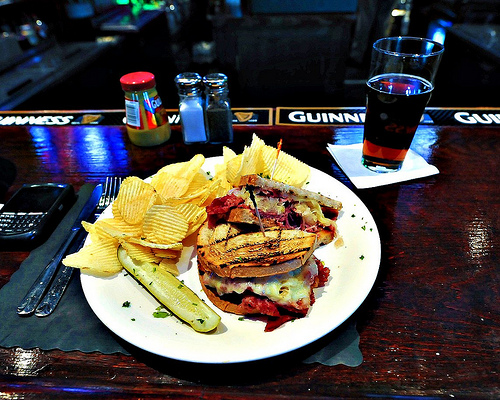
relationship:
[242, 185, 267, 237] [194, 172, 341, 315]
toothpick in sandwich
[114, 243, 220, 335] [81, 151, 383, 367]
pickle on plate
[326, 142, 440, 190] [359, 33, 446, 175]
napkin under drink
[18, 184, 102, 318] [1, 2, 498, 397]
knife on table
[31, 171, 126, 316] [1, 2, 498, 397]
fork on table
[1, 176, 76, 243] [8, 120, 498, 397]
cell phone on top of bar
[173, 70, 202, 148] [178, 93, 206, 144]
shaker of salt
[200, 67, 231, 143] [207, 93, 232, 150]
shaker of pepper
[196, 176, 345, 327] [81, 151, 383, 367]
sandwich on a plate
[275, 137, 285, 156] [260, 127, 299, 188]
top of toothpick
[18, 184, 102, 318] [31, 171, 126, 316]
knife beside fork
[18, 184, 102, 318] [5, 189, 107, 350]
knife on place mat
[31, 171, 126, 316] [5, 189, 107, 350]
fork on place mat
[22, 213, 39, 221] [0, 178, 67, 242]
buttons on cell phone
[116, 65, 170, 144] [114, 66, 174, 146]
condiment in jar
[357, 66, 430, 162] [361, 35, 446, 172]
liquid in glass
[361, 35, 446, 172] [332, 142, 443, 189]
glass on a napkin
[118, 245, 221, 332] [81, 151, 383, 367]
food on a plate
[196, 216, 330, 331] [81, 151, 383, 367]
food on a plate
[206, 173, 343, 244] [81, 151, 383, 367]
food on a plate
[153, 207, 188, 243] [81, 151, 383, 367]
food on a plate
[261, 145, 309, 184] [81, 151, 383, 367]
food on a plate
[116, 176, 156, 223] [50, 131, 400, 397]
chip on a plate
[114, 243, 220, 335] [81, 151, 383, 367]
pickle on a plate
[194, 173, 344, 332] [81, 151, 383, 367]
sandwich on plate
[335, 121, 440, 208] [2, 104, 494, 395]
napkin on table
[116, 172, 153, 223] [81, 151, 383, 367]
chip on plate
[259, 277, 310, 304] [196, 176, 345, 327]
cheese on sandwich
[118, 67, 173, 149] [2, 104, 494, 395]
mustard on table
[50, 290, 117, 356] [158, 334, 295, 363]
place mat under plate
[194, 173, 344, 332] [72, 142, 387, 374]
sandwich on plate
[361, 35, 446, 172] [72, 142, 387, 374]
glass next to plate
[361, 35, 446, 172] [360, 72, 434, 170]
glass containing beverage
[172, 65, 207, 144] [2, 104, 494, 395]
salt shaker on table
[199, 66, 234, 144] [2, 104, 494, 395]
pepper shaker on table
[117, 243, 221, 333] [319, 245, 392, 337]
pickle on plate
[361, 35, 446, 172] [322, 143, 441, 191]
glass on napkin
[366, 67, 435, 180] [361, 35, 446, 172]
soda in glass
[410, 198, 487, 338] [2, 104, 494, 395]
carpet on table